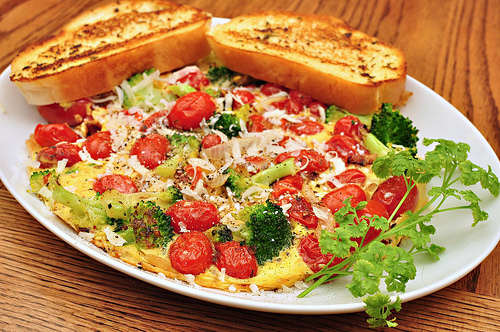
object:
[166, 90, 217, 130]
tomato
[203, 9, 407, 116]
bread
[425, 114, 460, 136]
plate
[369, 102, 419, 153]
broccoli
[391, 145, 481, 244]
sprig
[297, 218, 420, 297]
parsley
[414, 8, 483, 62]
table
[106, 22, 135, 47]
seasoning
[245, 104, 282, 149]
cheese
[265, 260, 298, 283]
eggs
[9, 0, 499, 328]
food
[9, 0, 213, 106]
bread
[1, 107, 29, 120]
part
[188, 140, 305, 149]
onion